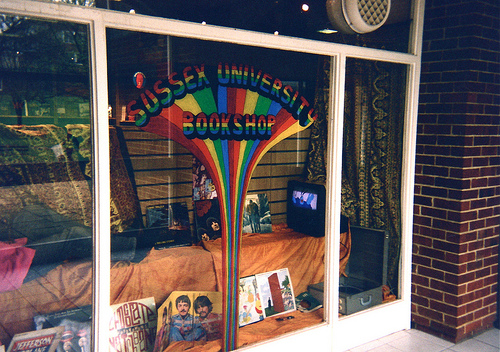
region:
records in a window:
[147, 260, 298, 342]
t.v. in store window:
[232, 166, 337, 268]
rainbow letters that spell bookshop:
[141, 106, 283, 138]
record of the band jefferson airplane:
[13, 328, 67, 350]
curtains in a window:
[301, 80, 411, 275]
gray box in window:
[294, 220, 401, 344]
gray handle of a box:
[340, 289, 377, 312]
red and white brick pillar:
[406, 98, 488, 343]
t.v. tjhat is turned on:
[249, 174, 344, 253]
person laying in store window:
[4, 201, 174, 294]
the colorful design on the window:
[126, 63, 318, 348]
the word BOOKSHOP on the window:
[181, 108, 275, 140]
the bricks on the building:
[410, 0, 497, 344]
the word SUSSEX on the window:
[126, 63, 210, 124]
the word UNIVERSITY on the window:
[215, 62, 317, 127]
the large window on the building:
[0, 0, 425, 350]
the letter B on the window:
[181, 110, 194, 135]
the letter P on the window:
[266, 113, 277, 140]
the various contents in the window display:
[0, 16, 407, 348]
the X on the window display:
[193, 62, 209, 88]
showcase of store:
[0, 0, 423, 347]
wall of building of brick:
[386, 0, 499, 340]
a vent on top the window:
[328, 2, 400, 34]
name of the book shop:
[108, 56, 335, 167]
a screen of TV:
[276, 174, 330, 239]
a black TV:
[281, 175, 328, 239]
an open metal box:
[333, 213, 393, 313]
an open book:
[228, 262, 300, 333]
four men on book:
[136, 285, 229, 350]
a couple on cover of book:
[241, 187, 280, 236]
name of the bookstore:
[119, 45, 337, 164]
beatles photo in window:
[160, 288, 225, 341]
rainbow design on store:
[202, 148, 252, 305]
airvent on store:
[340, 0, 399, 40]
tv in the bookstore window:
[287, 180, 323, 237]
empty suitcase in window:
[347, 216, 384, 307]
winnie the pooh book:
[240, 280, 265, 328]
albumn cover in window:
[150, 200, 195, 247]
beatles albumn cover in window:
[194, 198, 220, 246]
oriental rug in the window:
[5, 124, 91, 195]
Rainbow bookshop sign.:
[125, 64, 316, 344]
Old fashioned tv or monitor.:
[288, 182, 324, 240]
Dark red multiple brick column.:
[432, 52, 493, 314]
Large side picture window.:
[342, 56, 405, 320]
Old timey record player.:
[307, 226, 398, 308]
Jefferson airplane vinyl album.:
[9, 330, 59, 350]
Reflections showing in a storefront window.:
[4, 36, 93, 221]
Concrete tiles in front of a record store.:
[389, 334, 430, 349]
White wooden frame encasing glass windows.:
[89, 33, 412, 350]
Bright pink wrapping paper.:
[0, 236, 37, 296]